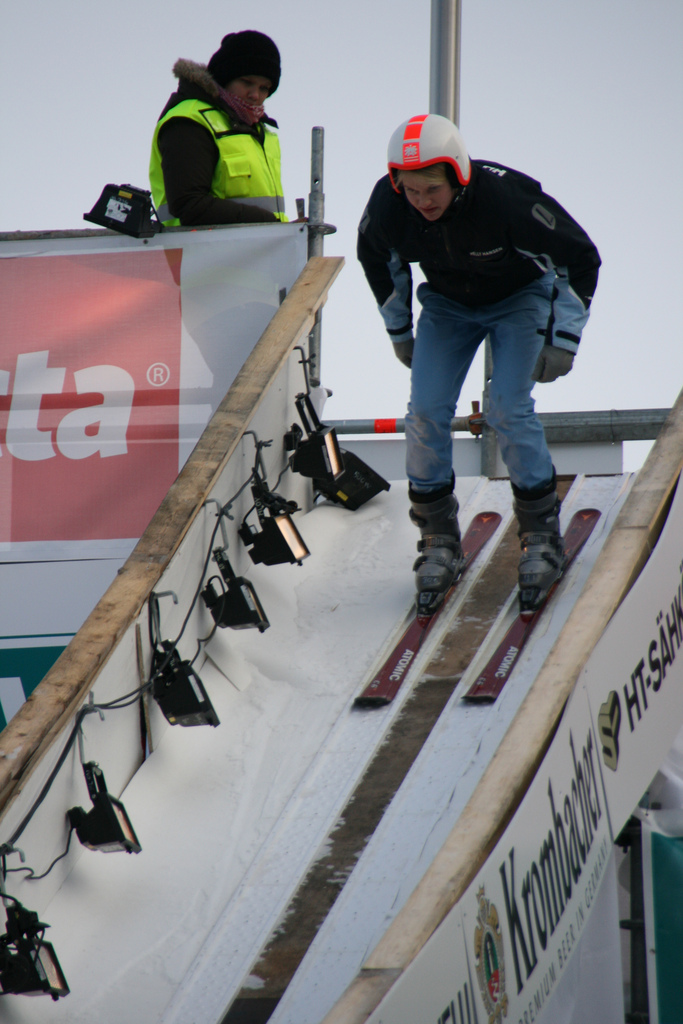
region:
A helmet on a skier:
[385, 113, 473, 208]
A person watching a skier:
[146, 29, 287, 222]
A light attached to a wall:
[64, 765, 139, 853]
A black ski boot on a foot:
[409, 494, 464, 617]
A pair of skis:
[352, 509, 602, 698]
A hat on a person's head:
[207, 30, 282, 95]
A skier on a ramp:
[355, 111, 603, 605]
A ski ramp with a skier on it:
[25, 470, 617, 1017]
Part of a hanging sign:
[0, 256, 181, 534]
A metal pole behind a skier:
[428, 9, 465, 122]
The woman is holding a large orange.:
[285, 872, 301, 898]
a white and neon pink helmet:
[385, 112, 471, 196]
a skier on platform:
[355, 111, 603, 707]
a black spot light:
[283, 424, 345, 483]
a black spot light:
[245, 513, 309, 567]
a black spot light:
[203, 577, 267, 630]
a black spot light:
[151, 662, 220, 730]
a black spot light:
[76, 796, 143, 856]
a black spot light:
[318, 446, 387, 511]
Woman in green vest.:
[150, 23, 286, 224]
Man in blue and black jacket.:
[350, 113, 599, 608]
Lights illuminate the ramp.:
[0, 337, 347, 1005]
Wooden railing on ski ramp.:
[0, 245, 342, 754]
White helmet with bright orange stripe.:
[382, 112, 470, 196]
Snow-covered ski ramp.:
[6, 462, 611, 1020]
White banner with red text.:
[0, 229, 311, 635]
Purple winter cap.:
[201, 25, 280, 95]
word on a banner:
[490, 752, 600, 937]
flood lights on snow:
[62, 762, 157, 871]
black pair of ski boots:
[402, 493, 566, 613]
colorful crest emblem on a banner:
[469, 897, 527, 1020]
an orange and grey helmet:
[382, 108, 480, 206]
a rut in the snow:
[215, 925, 301, 986]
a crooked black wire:
[9, 841, 82, 889]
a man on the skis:
[431, 180, 610, 441]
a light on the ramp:
[298, 391, 358, 513]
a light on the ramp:
[337, 414, 389, 550]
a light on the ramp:
[277, 487, 325, 584]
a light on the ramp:
[200, 537, 287, 652]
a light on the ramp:
[130, 658, 221, 730]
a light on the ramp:
[91, 738, 213, 937]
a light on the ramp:
[11, 898, 87, 1015]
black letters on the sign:
[509, 822, 557, 927]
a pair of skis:
[328, 445, 608, 750]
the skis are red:
[340, 476, 609, 732]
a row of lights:
[0, 292, 360, 996]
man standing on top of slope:
[7, 113, 598, 1005]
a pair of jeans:
[377, 289, 577, 516]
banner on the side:
[409, 554, 682, 1022]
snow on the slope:
[59, 619, 476, 987]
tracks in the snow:
[110, 662, 461, 1018]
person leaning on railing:
[112, 15, 351, 484]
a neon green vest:
[118, 96, 317, 236]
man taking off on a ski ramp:
[354, 114, 601, 619]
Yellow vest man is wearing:
[150, 87, 287, 233]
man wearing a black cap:
[150, 29, 293, 228]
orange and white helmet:
[387, 111, 474, 192]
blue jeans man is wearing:
[405, 281, 557, 488]